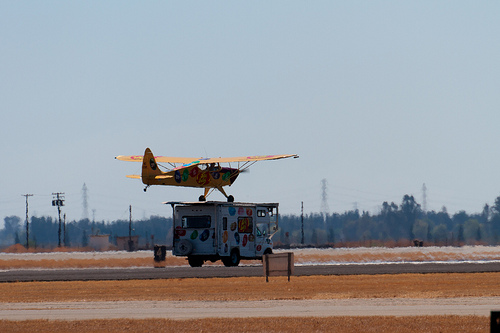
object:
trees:
[1, 193, 499, 247]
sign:
[263, 252, 294, 277]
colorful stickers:
[253, 243, 264, 253]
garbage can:
[152, 244, 168, 270]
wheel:
[199, 194, 205, 199]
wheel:
[226, 195, 234, 203]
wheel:
[142, 187, 147, 192]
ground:
[0, 247, 500, 332]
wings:
[206, 152, 301, 163]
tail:
[140, 146, 164, 184]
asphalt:
[326, 267, 361, 273]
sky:
[0, 0, 500, 231]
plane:
[113, 148, 300, 204]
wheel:
[222, 248, 241, 267]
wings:
[111, 153, 203, 163]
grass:
[0, 313, 488, 332]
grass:
[1, 272, 500, 301]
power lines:
[328, 184, 406, 201]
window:
[184, 213, 214, 231]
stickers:
[230, 245, 244, 257]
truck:
[161, 200, 280, 267]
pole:
[24, 194, 30, 248]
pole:
[56, 193, 63, 248]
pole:
[128, 203, 135, 238]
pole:
[298, 200, 307, 245]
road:
[0, 262, 500, 282]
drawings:
[197, 229, 214, 242]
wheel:
[187, 254, 206, 268]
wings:
[119, 173, 145, 180]